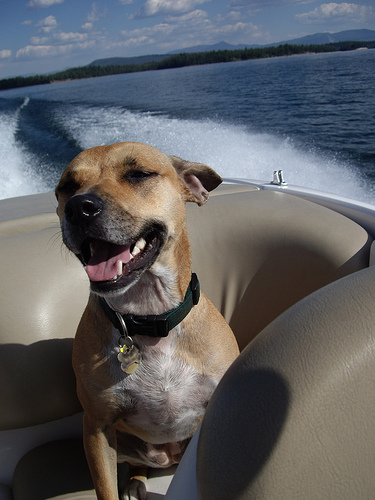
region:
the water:
[180, 121, 238, 158]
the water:
[224, 75, 308, 107]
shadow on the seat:
[223, 368, 300, 463]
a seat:
[286, 329, 373, 400]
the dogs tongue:
[89, 259, 113, 279]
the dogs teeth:
[132, 241, 143, 254]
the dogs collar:
[144, 314, 170, 334]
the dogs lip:
[101, 279, 112, 290]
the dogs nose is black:
[67, 197, 100, 222]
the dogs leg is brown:
[81, 451, 124, 499]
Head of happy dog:
[53, 139, 222, 300]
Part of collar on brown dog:
[90, 290, 207, 343]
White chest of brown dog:
[118, 367, 194, 424]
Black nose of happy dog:
[62, 198, 107, 226]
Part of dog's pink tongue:
[87, 260, 115, 277]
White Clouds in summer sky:
[29, 12, 81, 55]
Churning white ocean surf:
[207, 129, 262, 160]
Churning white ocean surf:
[280, 160, 323, 181]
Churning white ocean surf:
[8, 135, 39, 170]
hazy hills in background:
[189, 42, 219, 48]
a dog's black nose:
[70, 200, 99, 218]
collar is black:
[91, 291, 211, 323]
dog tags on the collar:
[113, 335, 142, 373]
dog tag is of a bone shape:
[114, 349, 142, 361]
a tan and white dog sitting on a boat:
[59, 155, 236, 498]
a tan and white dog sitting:
[54, 142, 233, 497]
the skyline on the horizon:
[25, 26, 359, 73]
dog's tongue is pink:
[87, 245, 118, 273]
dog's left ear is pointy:
[177, 157, 223, 202]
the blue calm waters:
[244, 63, 362, 116]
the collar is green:
[92, 297, 187, 352]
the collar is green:
[119, 280, 249, 357]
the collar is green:
[93, 271, 254, 430]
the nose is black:
[61, 192, 115, 232]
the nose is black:
[47, 184, 126, 254]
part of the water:
[319, 129, 324, 138]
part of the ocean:
[315, 177, 328, 199]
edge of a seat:
[255, 438, 264, 448]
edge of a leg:
[95, 446, 141, 494]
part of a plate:
[182, 470, 194, 482]